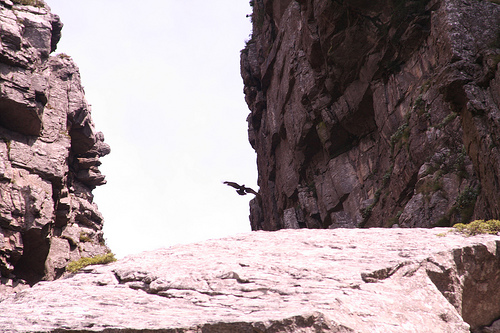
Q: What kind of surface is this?
A: Rock.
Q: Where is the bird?
A: Above the rock.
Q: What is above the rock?
A: Bird.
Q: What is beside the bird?
A: Rock wall.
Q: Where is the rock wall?
A: Beside the bird.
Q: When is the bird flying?
A: Day light.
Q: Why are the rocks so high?
A: Part of a cliff.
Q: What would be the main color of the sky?
A: White.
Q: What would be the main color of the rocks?
A: Brown.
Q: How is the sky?
A: Overcast.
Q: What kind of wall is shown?
A: Rock wall.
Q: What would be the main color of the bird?
A: Black.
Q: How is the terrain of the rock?
A: Rough.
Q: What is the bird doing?
A: Flying.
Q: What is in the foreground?
A: Rock.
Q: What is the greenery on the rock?
A: Mold.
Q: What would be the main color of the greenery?
A: Green.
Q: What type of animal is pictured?
A: A bird.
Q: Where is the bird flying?
A: In the sky.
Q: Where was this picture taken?
A: In a canyon.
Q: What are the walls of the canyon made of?
A: Rock.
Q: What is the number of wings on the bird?
A: Two.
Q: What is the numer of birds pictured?
A: One.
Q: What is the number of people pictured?
A: Zero.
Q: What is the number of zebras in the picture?
A: Zero.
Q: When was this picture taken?
A: Daytime.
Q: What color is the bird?
A: Black.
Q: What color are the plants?
A: Green.